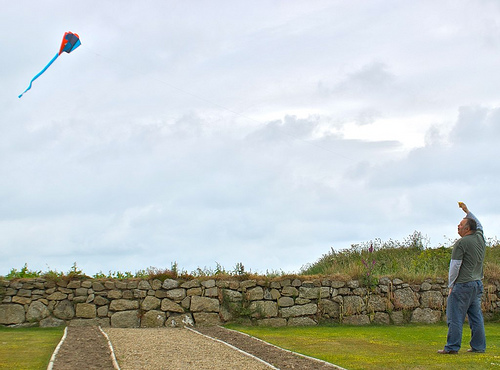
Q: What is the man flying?
A: A kite.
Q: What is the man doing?
A: Flying a kite.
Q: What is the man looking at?
A: The kite.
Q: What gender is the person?
A: Male.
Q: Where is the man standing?
A: In the grass.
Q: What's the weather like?
A: Cloudy.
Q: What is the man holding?
A: Kite string.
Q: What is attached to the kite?
A: String.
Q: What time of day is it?
A: Afternoon.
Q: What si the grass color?
A: Green.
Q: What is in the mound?
A: Grass.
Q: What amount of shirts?
A: Two.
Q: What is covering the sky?
A: Clouds.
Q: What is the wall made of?
A: Stones.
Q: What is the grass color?
A: Green.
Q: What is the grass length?
A: Tall.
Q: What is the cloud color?
A: White.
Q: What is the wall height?
A: Short.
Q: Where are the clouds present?
A: In the sky.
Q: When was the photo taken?
A: In the daytime.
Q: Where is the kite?
A: In the air.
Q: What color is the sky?
A: Blue.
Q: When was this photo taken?
A: During the day.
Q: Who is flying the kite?
A: The man.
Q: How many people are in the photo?
A: One.